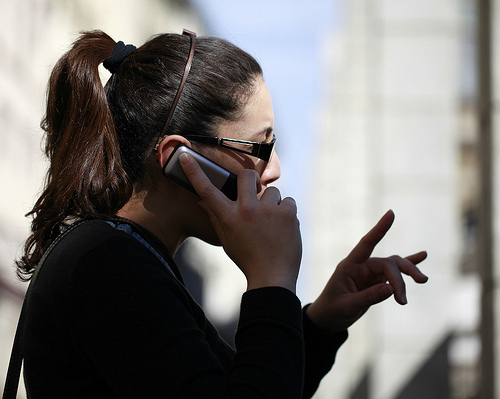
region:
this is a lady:
[0, 25, 363, 380]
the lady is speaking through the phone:
[27, 18, 333, 384]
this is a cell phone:
[161, 147, 229, 195]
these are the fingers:
[333, 208, 434, 308]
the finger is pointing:
[354, 203, 406, 259]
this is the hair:
[55, 70, 117, 199]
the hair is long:
[46, 65, 102, 202]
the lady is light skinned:
[253, 224, 289, 259]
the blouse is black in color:
[95, 282, 188, 363]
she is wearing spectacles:
[238, 134, 277, 156]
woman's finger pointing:
[338, 204, 404, 255]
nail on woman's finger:
[414, 271, 426, 280]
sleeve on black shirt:
[218, 278, 310, 308]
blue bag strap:
[116, 221, 199, 285]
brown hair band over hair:
[158, 19, 198, 133]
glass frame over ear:
[131, 128, 254, 154]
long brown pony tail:
[45, 23, 107, 265]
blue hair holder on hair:
[102, 35, 136, 67]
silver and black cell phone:
[157, 144, 262, 214]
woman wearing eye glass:
[221, 125, 302, 164]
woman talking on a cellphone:
[3, 21, 435, 397]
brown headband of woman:
[160, 21, 205, 130]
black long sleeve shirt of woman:
[21, 227, 325, 398]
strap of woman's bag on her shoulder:
[5, 217, 192, 398]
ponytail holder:
[99, 37, 136, 65]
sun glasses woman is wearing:
[196, 124, 281, 170]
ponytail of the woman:
[19, 33, 123, 242]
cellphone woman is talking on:
[163, 145, 257, 215]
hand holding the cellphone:
[179, 152, 304, 286]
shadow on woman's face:
[120, 150, 255, 262]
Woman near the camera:
[2, 30, 428, 397]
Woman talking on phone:
[2, 30, 429, 395]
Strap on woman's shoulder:
[2, 213, 182, 397]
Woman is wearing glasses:
[182, 133, 272, 168]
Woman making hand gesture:
[312, 210, 427, 331]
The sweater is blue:
[21, 214, 347, 396]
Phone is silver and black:
[165, 146, 260, 201]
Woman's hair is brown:
[15, 31, 261, 279]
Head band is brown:
[145, 29, 195, 165]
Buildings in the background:
[2, 0, 496, 397]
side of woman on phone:
[5, 25, 425, 397]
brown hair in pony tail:
[22, 29, 134, 261]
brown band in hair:
[134, 28, 258, 138]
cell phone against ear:
[166, 144, 234, 191]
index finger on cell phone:
[168, 151, 225, 196]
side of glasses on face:
[197, 129, 276, 162]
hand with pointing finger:
[313, 209, 426, 336]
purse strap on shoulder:
[6, 215, 181, 396]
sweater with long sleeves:
[23, 220, 348, 397]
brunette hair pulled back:
[13, 28, 258, 275]